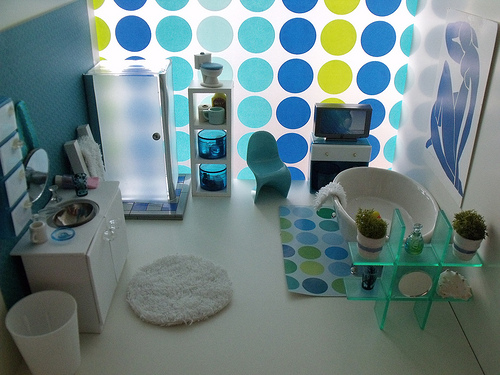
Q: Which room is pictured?
A: It is a bathroom.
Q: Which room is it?
A: It is a bathroom.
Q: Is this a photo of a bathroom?
A: Yes, it is showing a bathroom.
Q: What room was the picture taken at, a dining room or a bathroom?
A: It was taken at a bathroom.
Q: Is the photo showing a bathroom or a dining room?
A: It is showing a bathroom.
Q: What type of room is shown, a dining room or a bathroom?
A: It is a bathroom.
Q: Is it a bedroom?
A: No, it is a bathroom.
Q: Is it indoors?
A: Yes, it is indoors.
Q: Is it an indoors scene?
A: Yes, it is indoors.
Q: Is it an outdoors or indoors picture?
A: It is indoors.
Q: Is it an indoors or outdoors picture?
A: It is indoors.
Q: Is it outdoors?
A: No, it is indoors.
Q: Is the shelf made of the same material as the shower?
A: Yes, both the shelf and the shower are made of glass.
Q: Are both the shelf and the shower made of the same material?
A: Yes, both the shelf and the shower are made of glass.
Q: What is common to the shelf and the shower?
A: The material, both the shelf and the shower are glass.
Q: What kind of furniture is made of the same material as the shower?
A: The shelf is made of the same material as the shower.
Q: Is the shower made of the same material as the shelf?
A: Yes, both the shower and the shelf are made of glass.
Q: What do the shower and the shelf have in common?
A: The material, both the shower and the shelf are glass.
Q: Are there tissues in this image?
A: No, there are no tissues.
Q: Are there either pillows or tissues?
A: No, there are no tissues or pillows.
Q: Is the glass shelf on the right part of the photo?
A: Yes, the shelf is on the right of the image.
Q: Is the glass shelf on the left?
A: No, the shelf is on the right of the image.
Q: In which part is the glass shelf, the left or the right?
A: The shelf is on the right of the image.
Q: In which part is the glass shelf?
A: The shelf is on the right of the image.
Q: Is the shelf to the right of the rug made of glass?
A: Yes, the shelf is made of glass.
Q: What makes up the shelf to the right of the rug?
A: The shelf is made of glass.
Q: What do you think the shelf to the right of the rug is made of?
A: The shelf is made of glass.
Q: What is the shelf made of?
A: The shelf is made of glass.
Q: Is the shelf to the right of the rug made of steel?
A: No, the shelf is made of glass.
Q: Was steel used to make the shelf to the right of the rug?
A: No, the shelf is made of glass.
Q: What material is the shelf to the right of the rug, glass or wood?
A: The shelf is made of glass.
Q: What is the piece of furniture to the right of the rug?
A: The piece of furniture is a shelf.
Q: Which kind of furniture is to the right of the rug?
A: The piece of furniture is a shelf.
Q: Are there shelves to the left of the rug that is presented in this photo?
A: No, the shelf is to the right of the rug.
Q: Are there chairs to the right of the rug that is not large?
A: No, there is a shelf to the right of the rug.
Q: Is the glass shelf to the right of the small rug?
A: Yes, the shelf is to the right of the rug.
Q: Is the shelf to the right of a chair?
A: No, the shelf is to the right of the rug.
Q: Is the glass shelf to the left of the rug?
A: No, the shelf is to the right of the rug.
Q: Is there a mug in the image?
A: Yes, there is a mug.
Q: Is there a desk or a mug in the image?
A: Yes, there is a mug.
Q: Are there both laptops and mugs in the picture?
A: No, there is a mug but no laptops.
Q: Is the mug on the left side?
A: Yes, the mug is on the left of the image.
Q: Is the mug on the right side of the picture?
A: No, the mug is on the left of the image.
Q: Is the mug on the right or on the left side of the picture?
A: The mug is on the left of the image.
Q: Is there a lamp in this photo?
A: No, there are no lamps.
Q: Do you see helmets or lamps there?
A: No, there are no lamps or helmets.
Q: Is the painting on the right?
A: Yes, the painting is on the right of the image.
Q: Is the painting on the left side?
A: No, the painting is on the right of the image.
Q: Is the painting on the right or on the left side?
A: The painting is on the right of the image.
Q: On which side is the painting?
A: The painting is on the right of the image.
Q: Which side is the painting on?
A: The painting is on the right of the image.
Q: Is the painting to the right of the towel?
A: Yes, the painting is to the right of the towel.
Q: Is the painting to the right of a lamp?
A: No, the painting is to the right of the towel.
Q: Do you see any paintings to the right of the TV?
A: Yes, there is a painting to the right of the TV.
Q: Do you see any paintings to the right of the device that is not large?
A: Yes, there is a painting to the right of the TV.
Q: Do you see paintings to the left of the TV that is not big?
A: No, the painting is to the right of the TV.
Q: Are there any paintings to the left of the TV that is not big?
A: No, the painting is to the right of the TV.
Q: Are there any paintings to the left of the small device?
A: No, the painting is to the right of the TV.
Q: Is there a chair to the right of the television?
A: No, there is a painting to the right of the television.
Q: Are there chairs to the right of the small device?
A: No, there is a painting to the right of the television.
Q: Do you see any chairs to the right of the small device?
A: No, there is a painting to the right of the television.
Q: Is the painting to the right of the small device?
A: Yes, the painting is to the right of the TV.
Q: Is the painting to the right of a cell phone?
A: No, the painting is to the right of the TV.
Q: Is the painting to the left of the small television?
A: No, the painting is to the right of the television.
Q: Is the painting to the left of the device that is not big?
A: No, the painting is to the right of the television.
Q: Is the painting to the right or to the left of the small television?
A: The painting is to the right of the TV.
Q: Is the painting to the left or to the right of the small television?
A: The painting is to the right of the TV.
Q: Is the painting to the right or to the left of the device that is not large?
A: The painting is to the right of the TV.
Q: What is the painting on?
A: The painting is on the wall.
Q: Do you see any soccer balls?
A: No, there are no soccer balls.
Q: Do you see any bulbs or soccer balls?
A: No, there are no soccer balls or bulbs.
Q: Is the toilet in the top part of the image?
A: Yes, the toilet is in the top of the image.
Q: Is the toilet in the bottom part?
A: No, the toilet is in the top of the image.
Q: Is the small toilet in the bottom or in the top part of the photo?
A: The toilet is in the top of the image.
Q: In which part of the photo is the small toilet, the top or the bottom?
A: The toilet is in the top of the image.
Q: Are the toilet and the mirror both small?
A: Yes, both the toilet and the mirror are small.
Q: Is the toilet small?
A: Yes, the toilet is small.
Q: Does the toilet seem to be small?
A: Yes, the toilet is small.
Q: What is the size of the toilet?
A: The toilet is small.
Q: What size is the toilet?
A: The toilet is small.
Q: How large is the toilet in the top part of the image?
A: The toilet is small.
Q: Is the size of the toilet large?
A: No, the toilet is small.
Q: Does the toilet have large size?
A: No, the toilet is small.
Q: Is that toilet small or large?
A: The toilet is small.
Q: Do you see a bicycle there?
A: No, there are no bicycles.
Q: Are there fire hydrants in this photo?
A: No, there are no fire hydrants.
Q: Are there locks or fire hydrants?
A: No, there are no fire hydrants or locks.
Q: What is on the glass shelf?
A: The plants are on the shelf.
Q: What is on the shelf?
A: The plants are on the shelf.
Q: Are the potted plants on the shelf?
A: Yes, the plants are on the shelf.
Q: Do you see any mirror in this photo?
A: Yes, there is a mirror.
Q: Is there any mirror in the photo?
A: Yes, there is a mirror.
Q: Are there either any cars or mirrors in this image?
A: Yes, there is a mirror.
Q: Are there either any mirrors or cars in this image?
A: Yes, there is a mirror.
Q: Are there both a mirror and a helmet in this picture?
A: No, there is a mirror but no helmets.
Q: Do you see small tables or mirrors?
A: Yes, there is a small mirror.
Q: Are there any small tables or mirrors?
A: Yes, there is a small mirror.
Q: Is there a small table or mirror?
A: Yes, there is a small mirror.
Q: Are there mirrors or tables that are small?
A: Yes, the mirror is small.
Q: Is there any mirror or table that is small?
A: Yes, the mirror is small.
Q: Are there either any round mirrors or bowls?
A: Yes, there is a round mirror.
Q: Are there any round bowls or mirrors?
A: Yes, there is a round mirror.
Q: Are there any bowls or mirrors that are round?
A: Yes, the mirror is round.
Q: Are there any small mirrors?
A: Yes, there is a small mirror.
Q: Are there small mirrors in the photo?
A: Yes, there is a small mirror.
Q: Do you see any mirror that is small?
A: Yes, there is a mirror that is small.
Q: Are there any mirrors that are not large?
A: Yes, there is a small mirror.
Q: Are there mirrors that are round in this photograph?
A: Yes, there is a round mirror.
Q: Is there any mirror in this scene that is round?
A: Yes, there is a mirror that is round.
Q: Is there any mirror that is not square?
A: Yes, there is a round mirror.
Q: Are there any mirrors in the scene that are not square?
A: Yes, there is a round mirror.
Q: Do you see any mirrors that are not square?
A: Yes, there is a round mirror.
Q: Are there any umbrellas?
A: No, there are no umbrellas.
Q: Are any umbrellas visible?
A: No, there are no umbrellas.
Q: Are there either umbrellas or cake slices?
A: No, there are no umbrellas or cake slices.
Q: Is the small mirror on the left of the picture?
A: Yes, the mirror is on the left of the image.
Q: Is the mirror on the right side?
A: No, the mirror is on the left of the image.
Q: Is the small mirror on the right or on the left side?
A: The mirror is on the left of the image.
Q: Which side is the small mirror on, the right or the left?
A: The mirror is on the left of the image.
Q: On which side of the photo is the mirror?
A: The mirror is on the left of the image.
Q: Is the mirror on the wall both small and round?
A: Yes, the mirror is small and round.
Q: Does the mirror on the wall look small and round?
A: Yes, the mirror is small and round.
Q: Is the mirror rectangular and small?
A: No, the mirror is small but round.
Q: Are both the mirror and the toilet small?
A: Yes, both the mirror and the toilet are small.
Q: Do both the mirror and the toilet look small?
A: Yes, both the mirror and the toilet are small.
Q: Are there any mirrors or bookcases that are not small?
A: No, there is a mirror but it is small.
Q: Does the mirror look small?
A: Yes, the mirror is small.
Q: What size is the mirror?
A: The mirror is small.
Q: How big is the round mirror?
A: The mirror is small.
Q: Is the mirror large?
A: No, the mirror is small.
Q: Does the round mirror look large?
A: No, the mirror is small.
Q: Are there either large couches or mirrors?
A: No, there is a mirror but it is small.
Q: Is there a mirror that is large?
A: No, there is a mirror but it is small.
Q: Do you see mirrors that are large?
A: No, there is a mirror but it is small.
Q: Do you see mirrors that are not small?
A: No, there is a mirror but it is small.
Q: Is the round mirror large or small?
A: The mirror is small.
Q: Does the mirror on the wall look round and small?
A: Yes, the mirror is round and small.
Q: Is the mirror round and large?
A: No, the mirror is round but small.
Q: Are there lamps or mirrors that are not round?
A: No, there is a mirror but it is round.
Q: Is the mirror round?
A: Yes, the mirror is round.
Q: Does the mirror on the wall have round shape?
A: Yes, the mirror is round.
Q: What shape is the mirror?
A: The mirror is round.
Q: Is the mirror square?
A: No, the mirror is round.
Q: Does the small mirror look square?
A: No, the mirror is round.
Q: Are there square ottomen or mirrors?
A: No, there is a mirror but it is round.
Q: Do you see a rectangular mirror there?
A: No, there is a mirror but it is round.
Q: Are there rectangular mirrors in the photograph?
A: No, there is a mirror but it is round.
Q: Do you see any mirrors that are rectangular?
A: No, there is a mirror but it is round.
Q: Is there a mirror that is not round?
A: No, there is a mirror but it is round.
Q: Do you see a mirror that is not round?
A: No, there is a mirror but it is round.